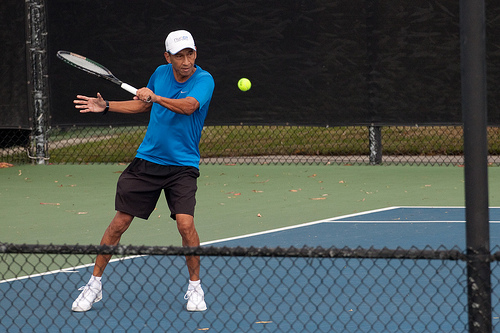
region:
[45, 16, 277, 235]
A man hitting a tennis ball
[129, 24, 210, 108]
A man with a hat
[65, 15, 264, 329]
A man on a tennis court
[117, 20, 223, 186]
A man with a blue shirt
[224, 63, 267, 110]
A tennis ball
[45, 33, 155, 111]
A tennis racket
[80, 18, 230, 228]
A man wearing black shorts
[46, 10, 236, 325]
A man wearing white shoes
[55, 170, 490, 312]
A blue and green tennis court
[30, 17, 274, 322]
A man watching a tennis ball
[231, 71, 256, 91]
Neon tennis ball in the air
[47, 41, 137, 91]
Black tennis racket in man's left hand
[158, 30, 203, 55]
White baseball cap on man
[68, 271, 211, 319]
White tennis shoes on man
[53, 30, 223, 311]
Man playing tennis on tennis court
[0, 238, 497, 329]
Fence on the tennis court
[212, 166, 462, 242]
Blue, white, and green tennis court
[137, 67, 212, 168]
Blue Nike shirt on man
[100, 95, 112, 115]
Black wristwatch on man's right wrist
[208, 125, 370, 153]
Grass in the distance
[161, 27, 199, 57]
The white hat the player is wearing.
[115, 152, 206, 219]
The black shorts the player is wearing.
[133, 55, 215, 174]
The blue shirt the player is wearing.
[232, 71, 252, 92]
The green tennis ball in the air.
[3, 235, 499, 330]
The chained link fence in front of the man.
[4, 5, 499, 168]
The chained linked fence behind the man.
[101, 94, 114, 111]
The black watch on the man's left wrist.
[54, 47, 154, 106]
The black and white tennis racket in the player's hand.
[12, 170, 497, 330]
The blue court the player is standing on.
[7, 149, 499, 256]
The green court behind the player.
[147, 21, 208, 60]
A white cap on a man's head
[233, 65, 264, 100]
A tennis ball flying through the air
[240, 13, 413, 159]
A chain link fence around a tennis court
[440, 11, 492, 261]
A tall pole supporting a fence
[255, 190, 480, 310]
A blue tennis court with white lines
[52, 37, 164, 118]
A tennis racket in a man's hand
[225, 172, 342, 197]
Fallen leaves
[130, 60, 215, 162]
A man wearing a blue shirt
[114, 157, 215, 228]
Black shorts on a tennis player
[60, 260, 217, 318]
White shoes on a man's feet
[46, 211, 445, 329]
Man on tennis court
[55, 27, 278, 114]
Man swing at ball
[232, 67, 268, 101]
Yellow tennis ball in air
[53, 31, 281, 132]
Man swinging at tennis ball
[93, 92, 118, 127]
Man with watch on wrist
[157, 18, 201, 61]
Man wearing ball cap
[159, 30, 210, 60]
Man wearing white cap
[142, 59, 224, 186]
Man wearing blue T shirt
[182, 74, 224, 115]
T shirt has short sleeve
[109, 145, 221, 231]
Man wearing black shorts